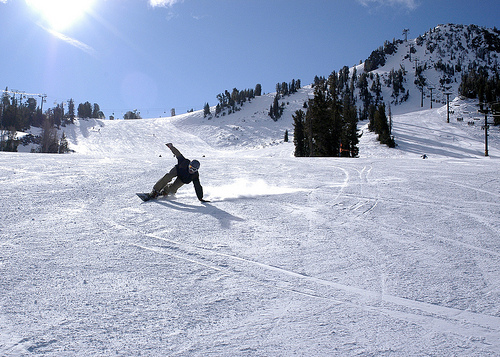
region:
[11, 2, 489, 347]
Photo taken during the day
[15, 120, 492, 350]
The ground is white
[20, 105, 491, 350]
The ground is covered in snow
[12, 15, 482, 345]
Photo taken in the winter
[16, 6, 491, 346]
The weather is cold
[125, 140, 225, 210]
Person on a snowboard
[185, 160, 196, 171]
Goggles on the man's face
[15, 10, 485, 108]
The sky is clear and blue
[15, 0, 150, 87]
Rays of sunshine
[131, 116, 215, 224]
man on snow board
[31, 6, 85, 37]
sun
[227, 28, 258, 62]
white clouds in blue sky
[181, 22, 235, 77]
white clouds in blue sky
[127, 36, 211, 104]
white clouds in blue sky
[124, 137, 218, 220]
A snowboarder coming down a slope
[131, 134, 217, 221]
A snowboarder coming down a slope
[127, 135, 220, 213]
A snowboarder coming down a slope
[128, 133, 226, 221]
A snowboarder coming down a slope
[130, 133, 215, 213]
A snowboarder coming down a slope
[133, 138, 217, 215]
A snowboarder coming down a slope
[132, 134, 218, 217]
A snowboarder coming down a slope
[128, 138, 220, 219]
A snowboarder coming down a slope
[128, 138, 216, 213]
A snowboarder coming down a slope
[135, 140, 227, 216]
A snowboarder coming down a slope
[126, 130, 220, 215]
A snowboarder coming down a slope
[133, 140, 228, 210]
A snowboarder coming down a slope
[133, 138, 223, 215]
A snowboarder coming down a slope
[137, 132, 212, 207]
the snowboarder on the hill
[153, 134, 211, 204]
the man leaning over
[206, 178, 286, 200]
the hand cutting through the snow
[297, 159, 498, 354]
the lines in the snow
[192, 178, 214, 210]
the hand on the ground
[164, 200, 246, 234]
the shadow on the hill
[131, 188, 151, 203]
the tip of the snowboard under the man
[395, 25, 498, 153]
the ski lift going up the mountain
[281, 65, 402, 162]
the trees on the snowy hill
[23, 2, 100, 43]
the glaring sun in the air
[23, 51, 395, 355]
the man is snowboarding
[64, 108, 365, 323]
the snow is fresh and smooth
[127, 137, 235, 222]
A person falling in the snow.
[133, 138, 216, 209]
A person snowboarding.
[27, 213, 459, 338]
The snow is white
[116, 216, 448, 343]
Ski marks in the snow.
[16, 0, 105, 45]
The sun is shining.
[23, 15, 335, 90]
The sky is clear and blue.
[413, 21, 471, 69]
Trees on top of the mountain.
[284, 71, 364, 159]
Green trees on the ground.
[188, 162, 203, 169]
The person is wearing goggles.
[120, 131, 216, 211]
man snowboarding on white snowy hill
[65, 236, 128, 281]
white snow on hill side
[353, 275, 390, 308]
white snow on hill side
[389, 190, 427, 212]
white snow on hill side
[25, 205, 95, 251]
white snow on hill side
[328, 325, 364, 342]
white snow on hill side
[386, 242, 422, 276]
white snow on hill side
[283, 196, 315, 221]
white snow on hill side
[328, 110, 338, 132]
green leaves on the tree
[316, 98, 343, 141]
green leaves on the tree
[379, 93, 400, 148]
green leaves on the tree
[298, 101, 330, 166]
green leaves on the tree